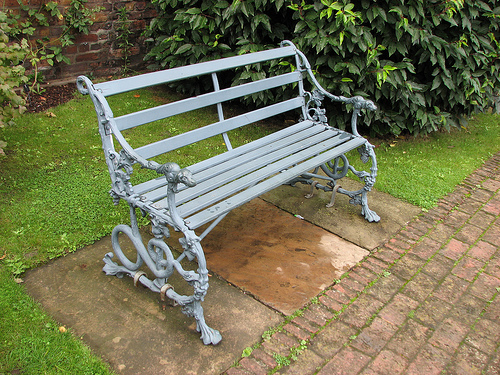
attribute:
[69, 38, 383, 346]
bench — gray, wood, metal, blue, siiting, sitting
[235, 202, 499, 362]
moss — green, growing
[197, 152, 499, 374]
bricks — red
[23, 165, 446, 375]
ground — concrete, bricked, cement, stone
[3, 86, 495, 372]
grass — green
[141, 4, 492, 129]
bush — thick, sitting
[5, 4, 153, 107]
wall — bricked